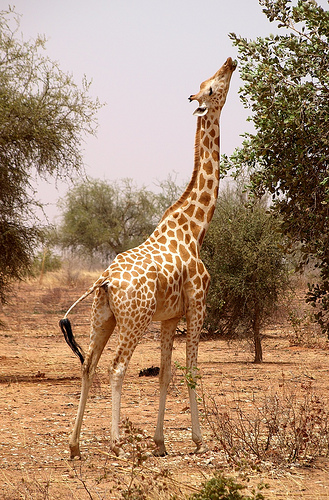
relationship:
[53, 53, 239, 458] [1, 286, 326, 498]
giraffe standing in dirt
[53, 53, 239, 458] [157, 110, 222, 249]
giraffe craning neck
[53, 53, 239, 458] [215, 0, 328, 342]
giraffe eating leaves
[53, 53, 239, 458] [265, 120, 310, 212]
giraffe eating leaves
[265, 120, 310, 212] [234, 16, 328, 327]
leaves on trees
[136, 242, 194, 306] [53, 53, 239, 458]
spots on giraffe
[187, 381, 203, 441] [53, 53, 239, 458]
white leg of giraffe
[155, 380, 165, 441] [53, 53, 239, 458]
white leg of giraffe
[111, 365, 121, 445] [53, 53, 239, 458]
white leg of giraffe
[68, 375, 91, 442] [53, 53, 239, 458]
white leg of giraffe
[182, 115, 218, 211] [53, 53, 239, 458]
neck of giraffe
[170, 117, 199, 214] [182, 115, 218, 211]
fringe on neck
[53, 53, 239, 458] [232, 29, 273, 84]
giraffe eating leaves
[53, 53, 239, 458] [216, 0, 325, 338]
giraffe grazing on tree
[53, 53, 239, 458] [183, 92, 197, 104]
giraffe has horns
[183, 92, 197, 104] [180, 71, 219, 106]
horns on head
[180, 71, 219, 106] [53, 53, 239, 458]
head of giraffe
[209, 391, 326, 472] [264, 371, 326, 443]
bush with leaves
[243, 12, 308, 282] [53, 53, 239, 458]
trees behind giraffe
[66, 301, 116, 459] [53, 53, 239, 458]
leg of giraffe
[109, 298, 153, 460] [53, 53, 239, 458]
leg of giraffe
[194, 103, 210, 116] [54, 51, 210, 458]
ear of giraffe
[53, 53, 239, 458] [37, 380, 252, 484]
giraffe standing on field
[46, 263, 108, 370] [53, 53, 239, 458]
skinny tail on back of giraffe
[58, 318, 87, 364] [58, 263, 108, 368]
hair on end skinny tail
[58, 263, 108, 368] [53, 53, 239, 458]
skinny tail on giraffe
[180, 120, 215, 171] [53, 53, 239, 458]
mane on back of giraffe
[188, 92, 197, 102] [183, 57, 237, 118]
horns on top head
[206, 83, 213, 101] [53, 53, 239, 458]
eye on giraffe